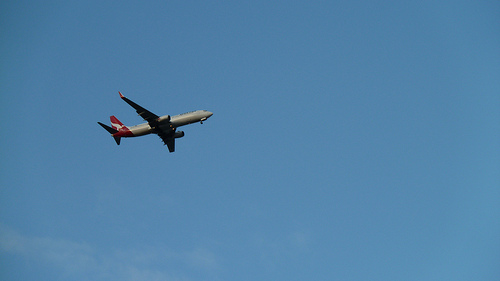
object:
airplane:
[96, 90, 214, 153]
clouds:
[0, 234, 220, 281]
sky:
[0, 0, 499, 281]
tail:
[110, 115, 131, 130]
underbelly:
[147, 117, 174, 134]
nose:
[204, 110, 214, 119]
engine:
[156, 115, 172, 123]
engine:
[174, 130, 186, 138]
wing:
[155, 128, 176, 153]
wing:
[119, 93, 159, 124]